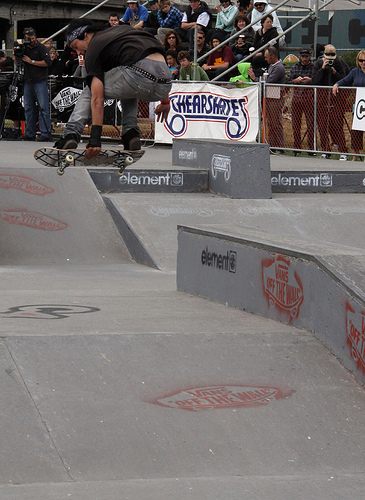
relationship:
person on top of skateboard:
[49, 17, 175, 155] [35, 147, 148, 177]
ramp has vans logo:
[6, 333, 365, 481] [152, 379, 289, 409]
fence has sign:
[175, 77, 365, 162] [154, 84, 262, 144]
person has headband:
[49, 17, 175, 155] [63, 25, 86, 44]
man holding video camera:
[11, 24, 52, 142] [13, 37, 35, 58]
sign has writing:
[154, 84, 262, 144] [171, 92, 250, 130]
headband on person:
[63, 25, 86, 44] [49, 17, 175, 155]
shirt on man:
[288, 61, 317, 99] [285, 50, 317, 156]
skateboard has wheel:
[35, 147, 148, 177] [123, 156, 133, 167]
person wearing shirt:
[49, 17, 175, 155] [81, 26, 165, 80]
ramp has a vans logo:
[6, 333, 365, 481] [152, 379, 289, 409]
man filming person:
[11, 24, 52, 142] [49, 17, 175, 155]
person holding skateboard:
[49, 17, 175, 155] [35, 147, 148, 177]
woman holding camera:
[312, 45, 347, 158] [325, 55, 337, 69]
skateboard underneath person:
[35, 147, 148, 177] [49, 17, 175, 155]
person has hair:
[49, 17, 175, 155] [53, 19, 93, 40]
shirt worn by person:
[81, 26, 165, 80] [49, 17, 175, 155]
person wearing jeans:
[49, 17, 175, 155] [62, 70, 180, 134]